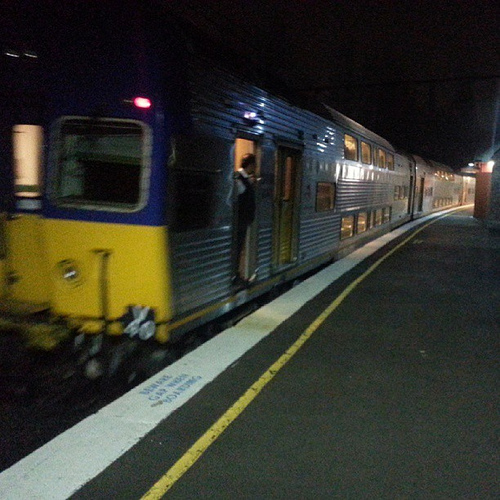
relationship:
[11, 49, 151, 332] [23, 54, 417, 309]
front of train car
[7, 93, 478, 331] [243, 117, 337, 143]
train long silver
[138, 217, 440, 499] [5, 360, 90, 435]
line along tracks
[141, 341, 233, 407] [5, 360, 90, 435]
white stripe along tracks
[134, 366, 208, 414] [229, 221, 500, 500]
writing on platform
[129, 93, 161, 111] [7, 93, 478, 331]
light of train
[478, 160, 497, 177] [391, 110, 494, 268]
light from station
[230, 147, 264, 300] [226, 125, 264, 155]
engineer standing at door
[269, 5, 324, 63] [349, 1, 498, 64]
night black sky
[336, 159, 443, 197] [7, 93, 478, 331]
reflection on side train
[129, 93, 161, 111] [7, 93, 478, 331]
light on train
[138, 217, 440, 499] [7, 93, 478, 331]
line beside train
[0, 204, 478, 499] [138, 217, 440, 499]
white stripe beside line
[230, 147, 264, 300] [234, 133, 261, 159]
person standing in doorway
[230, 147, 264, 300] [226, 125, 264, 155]
person holding door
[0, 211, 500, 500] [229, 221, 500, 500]
platform near platform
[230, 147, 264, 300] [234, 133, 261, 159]
person in doorway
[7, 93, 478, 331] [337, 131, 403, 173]
train has windows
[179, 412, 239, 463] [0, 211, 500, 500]
line on platform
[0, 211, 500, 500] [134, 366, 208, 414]
platform has writing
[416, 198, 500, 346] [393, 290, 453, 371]
zero passengers waiting waiting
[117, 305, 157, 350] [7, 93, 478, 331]
letters on train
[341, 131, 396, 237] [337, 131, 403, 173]
layers of windows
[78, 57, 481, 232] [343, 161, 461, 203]
train cars hooked together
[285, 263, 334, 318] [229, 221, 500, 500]
edge of platform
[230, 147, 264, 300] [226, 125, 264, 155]
man standing at door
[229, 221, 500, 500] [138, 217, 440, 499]
platform with line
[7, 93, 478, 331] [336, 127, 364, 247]
train has two levels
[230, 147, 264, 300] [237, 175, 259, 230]
man wearing vest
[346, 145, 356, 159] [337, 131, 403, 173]
passengers next to windows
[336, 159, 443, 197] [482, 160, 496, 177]
reflection of light